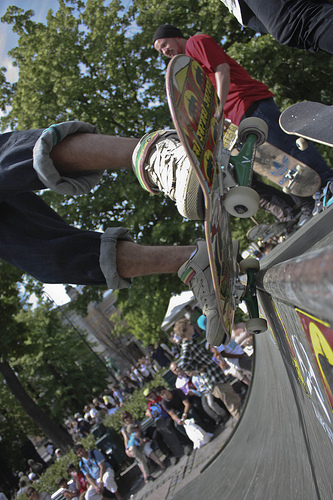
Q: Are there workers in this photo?
A: No, there are no workers.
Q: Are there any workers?
A: No, there are no workers.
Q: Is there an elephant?
A: No, there are no elephants.